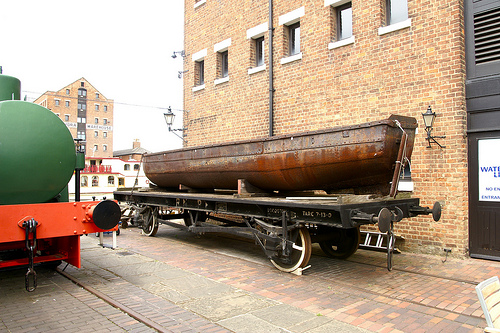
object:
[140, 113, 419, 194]
boat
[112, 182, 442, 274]
carrier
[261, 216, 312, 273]
front wheel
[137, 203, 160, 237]
back wheel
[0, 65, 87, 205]
tank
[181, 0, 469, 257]
building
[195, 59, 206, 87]
windows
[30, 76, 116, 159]
building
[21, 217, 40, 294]
chain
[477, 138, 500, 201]
sign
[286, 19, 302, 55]
window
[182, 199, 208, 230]
right wheel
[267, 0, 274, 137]
pole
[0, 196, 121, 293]
trailer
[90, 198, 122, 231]
circle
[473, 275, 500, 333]
chair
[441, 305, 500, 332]
corner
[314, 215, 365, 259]
wheels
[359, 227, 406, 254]
ladder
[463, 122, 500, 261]
door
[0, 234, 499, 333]
road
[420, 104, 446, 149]
lamp